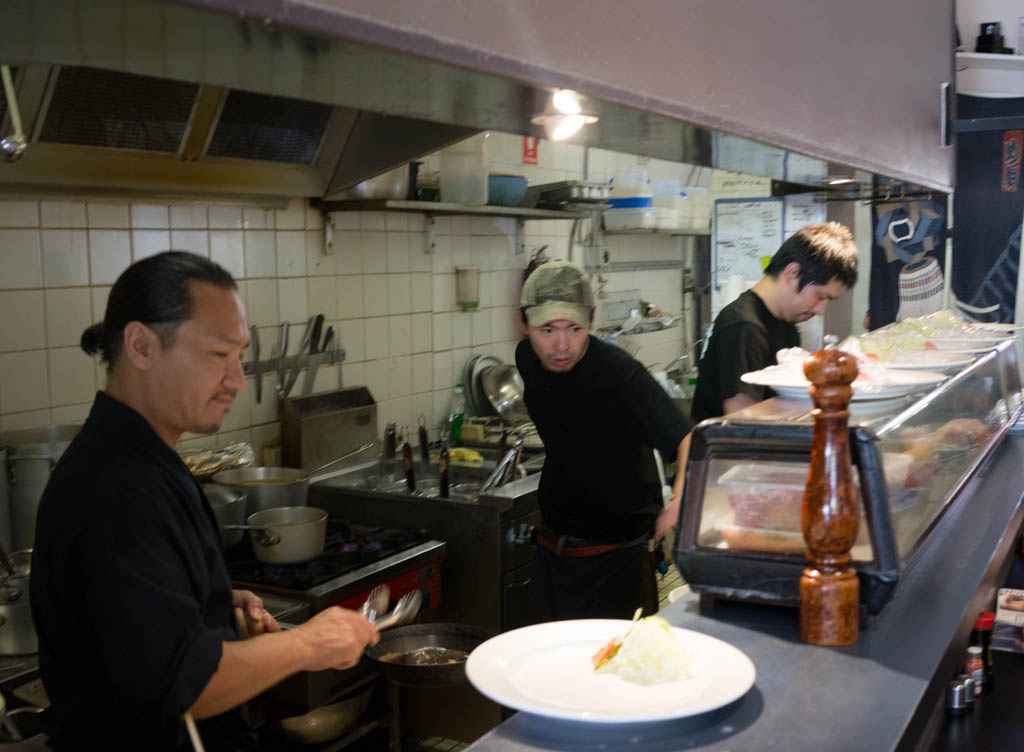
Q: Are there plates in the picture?
A: Yes, there is a plate.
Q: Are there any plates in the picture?
A: Yes, there is a plate.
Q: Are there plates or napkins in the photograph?
A: Yes, there is a plate.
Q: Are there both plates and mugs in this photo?
A: No, there is a plate but no mugs.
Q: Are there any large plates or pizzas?
A: Yes, there is a large plate.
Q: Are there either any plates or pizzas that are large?
A: Yes, the plate is large.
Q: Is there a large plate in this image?
A: Yes, there is a large plate.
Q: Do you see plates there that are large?
A: Yes, there is a plate that is large.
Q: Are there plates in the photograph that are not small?
A: Yes, there is a large plate.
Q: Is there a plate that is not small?
A: Yes, there is a large plate.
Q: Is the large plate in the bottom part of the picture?
A: Yes, the plate is in the bottom of the image.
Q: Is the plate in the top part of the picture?
A: No, the plate is in the bottom of the image.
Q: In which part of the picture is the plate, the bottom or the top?
A: The plate is in the bottom of the image.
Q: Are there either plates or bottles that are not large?
A: No, there is a plate but it is large.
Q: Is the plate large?
A: Yes, the plate is large.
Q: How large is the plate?
A: The plate is large.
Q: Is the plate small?
A: No, the plate is large.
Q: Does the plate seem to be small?
A: No, the plate is large.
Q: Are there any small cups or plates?
A: No, there is a plate but it is large.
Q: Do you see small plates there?
A: No, there is a plate but it is large.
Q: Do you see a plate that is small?
A: No, there is a plate but it is large.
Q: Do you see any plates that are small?
A: No, there is a plate but it is large.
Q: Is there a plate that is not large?
A: No, there is a plate but it is large.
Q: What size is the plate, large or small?
A: The plate is large.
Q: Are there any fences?
A: No, there are no fences.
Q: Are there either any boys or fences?
A: No, there are no fences or boys.